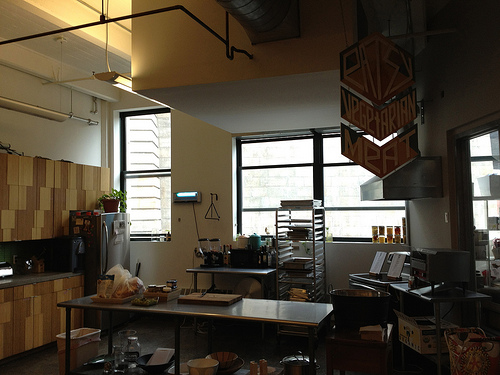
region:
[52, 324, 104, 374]
A wastebasket is sitting on a floor.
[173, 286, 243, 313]
A wood board is sitting on a table.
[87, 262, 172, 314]
Food is sitting on a table.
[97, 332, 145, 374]
Glass jars are sitting on a bottom shelf of a table.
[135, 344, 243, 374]
Three bowls are sitting on a lower shelf of a table.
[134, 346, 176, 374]
The color of a bowl is black.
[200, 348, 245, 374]
The color of a bowl is brown.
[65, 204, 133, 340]
A refrigerator is in the background.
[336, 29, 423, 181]
A sign is hanging from the ceiling.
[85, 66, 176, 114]
A fluorescent light is on.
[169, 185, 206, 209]
light on wall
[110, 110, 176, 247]
window on wall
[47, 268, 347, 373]
long table in room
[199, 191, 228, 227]
hanger on wall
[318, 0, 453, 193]
siign hanging from ceiling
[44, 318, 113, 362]
white trash bag in trash can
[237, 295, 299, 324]
reflection on table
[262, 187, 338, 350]
metal rack of trays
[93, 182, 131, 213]
flower pot on top of refrigerator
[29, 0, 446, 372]
Interior of restaurant kitchen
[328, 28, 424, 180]
Eatsy Vegetarian Meat sign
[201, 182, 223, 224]
Coat hanger attached to wall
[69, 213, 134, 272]
Silver metallic refrigerator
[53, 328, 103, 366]
Tan trash bin with white lining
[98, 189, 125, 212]
Leafy plant in planter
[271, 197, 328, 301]
Metal rack container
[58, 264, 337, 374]
Metallic table in kitchen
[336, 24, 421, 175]
Meat sign hanging high.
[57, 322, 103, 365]
Trash can with plastic bag.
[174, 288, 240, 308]
Wooden cutting board on table.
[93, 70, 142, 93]
Light fixture hanging from ceiling.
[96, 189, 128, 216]
Green potted plant on top of fridge.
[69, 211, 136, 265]
Stainless steel fridge with magnets.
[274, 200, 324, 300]
Silver food rack near window.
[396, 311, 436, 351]
Open box under shelf.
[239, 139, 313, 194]
Natural light coming through window.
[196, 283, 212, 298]
Knife on top of cutting board.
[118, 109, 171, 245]
the interior side of a window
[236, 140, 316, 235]
the interior side of a window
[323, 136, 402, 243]
the interior side of a window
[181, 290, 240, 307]
a wooden chopping block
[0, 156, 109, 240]
wooden cabinets on a wall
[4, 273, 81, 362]
wooden cabinets on a wall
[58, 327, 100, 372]
a trashcan on the ground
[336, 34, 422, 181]
a sign in a kitchen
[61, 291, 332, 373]
a large metal table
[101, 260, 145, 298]
a plastic bag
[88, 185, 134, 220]
a flower pot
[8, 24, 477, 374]
a scene during the day time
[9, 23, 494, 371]
a scene inside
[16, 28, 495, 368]
a scene inside a kitchen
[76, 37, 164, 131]
a light hanging on ceiling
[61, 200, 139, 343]
a silver icebox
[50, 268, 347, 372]
a silver table